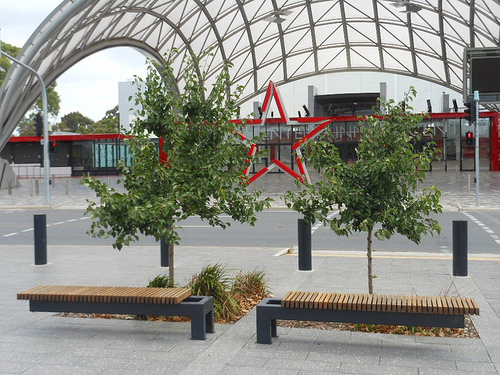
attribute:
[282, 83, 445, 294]
tree — thin, leafy, small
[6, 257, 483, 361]
pavement — stone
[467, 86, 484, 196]
silver pole — thin, tall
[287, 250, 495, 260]
line — yellow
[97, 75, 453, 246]
leaves — green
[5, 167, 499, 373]
ground — concrete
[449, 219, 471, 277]
pole — black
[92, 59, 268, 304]
tree — leafy, thin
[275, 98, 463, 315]
tree — leafy, thin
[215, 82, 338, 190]
star — red, decorative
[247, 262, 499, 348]
bench — wooden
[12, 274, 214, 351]
bench — short, wooden, black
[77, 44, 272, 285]
tree — small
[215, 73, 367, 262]
star — wire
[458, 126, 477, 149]
traffic sign — black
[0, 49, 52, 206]
pole — telephone pole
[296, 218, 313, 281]
pole — black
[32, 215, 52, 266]
pole — black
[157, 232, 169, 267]
pole — black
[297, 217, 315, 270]
pole — black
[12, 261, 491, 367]
sidewalk — concrete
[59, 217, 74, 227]
lines — white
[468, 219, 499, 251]
broken line — white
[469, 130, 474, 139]
traffic light — red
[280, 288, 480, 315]
slats — wooden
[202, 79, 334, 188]
star — large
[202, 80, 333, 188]
star statue — metal, red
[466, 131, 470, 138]
light — red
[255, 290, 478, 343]
bench — blue, wooden